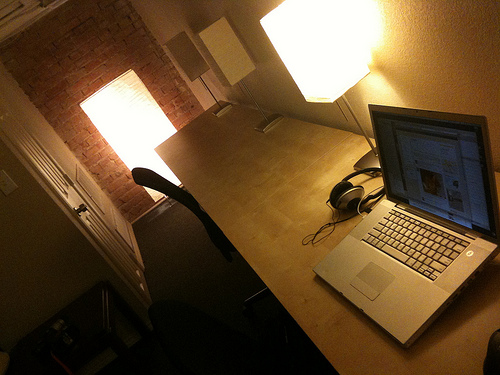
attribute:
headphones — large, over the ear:
[301, 167, 383, 245]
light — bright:
[258, 0, 388, 104]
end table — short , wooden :
[6, 280, 156, 373]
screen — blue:
[369, 112, 495, 222]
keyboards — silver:
[368, 208, 456, 280]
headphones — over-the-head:
[313, 168, 440, 235]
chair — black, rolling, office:
[122, 164, 233, 263]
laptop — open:
[273, 102, 499, 336]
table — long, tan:
[144, 62, 499, 366]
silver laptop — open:
[311, 107, 498, 347]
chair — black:
[129, 166, 237, 258]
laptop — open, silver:
[306, 98, 498, 351]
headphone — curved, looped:
[300, 165, 385, 246]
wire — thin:
[300, 197, 365, 246]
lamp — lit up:
[252, 0, 388, 179]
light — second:
[189, 12, 286, 133]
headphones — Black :
[315, 162, 385, 228]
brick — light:
[22, 37, 182, 219]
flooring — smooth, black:
[106, 187, 333, 374]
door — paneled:
[0, 100, 157, 320]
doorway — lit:
[77, 67, 197, 198]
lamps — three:
[262, 16, 379, 122]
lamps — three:
[194, 22, 258, 93]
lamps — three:
[163, 27, 206, 94]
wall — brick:
[0, 3, 207, 211]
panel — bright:
[68, 57, 189, 200]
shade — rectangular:
[157, 27, 207, 83]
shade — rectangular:
[190, 14, 255, 86]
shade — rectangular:
[255, 5, 381, 125]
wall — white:
[2, 142, 150, 362]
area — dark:
[0, 281, 155, 371]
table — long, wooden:
[153, 98, 481, 360]